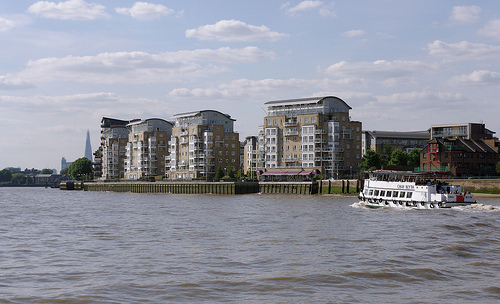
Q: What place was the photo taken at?
A: It was taken at the river.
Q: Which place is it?
A: It is a river.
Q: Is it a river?
A: Yes, it is a river.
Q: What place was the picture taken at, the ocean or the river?
A: It was taken at the river.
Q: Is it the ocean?
A: No, it is the river.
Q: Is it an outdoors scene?
A: Yes, it is outdoors.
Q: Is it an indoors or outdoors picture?
A: It is outdoors.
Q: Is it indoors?
A: No, it is outdoors.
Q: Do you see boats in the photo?
A: Yes, there is a boat.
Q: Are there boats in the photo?
A: Yes, there is a boat.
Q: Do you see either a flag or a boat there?
A: Yes, there is a boat.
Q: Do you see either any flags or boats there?
A: Yes, there is a boat.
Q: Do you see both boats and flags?
A: No, there is a boat but no flags.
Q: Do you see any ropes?
A: No, there are no ropes.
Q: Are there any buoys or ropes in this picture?
A: No, there are no ropes or buoys.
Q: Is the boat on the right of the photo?
A: Yes, the boat is on the right of the image.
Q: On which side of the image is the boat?
A: The boat is on the right of the image.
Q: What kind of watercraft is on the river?
A: The watercraft is a boat.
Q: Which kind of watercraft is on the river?
A: The watercraft is a boat.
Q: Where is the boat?
A: The boat is on the river.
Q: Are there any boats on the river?
A: Yes, there is a boat on the river.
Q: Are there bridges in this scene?
A: No, there are no bridges.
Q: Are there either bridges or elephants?
A: No, there are no bridges or elephants.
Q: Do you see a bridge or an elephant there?
A: No, there are no bridges or elephants.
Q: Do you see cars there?
A: No, there are no cars.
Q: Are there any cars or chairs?
A: No, there are no cars or chairs.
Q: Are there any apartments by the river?
A: Yes, there is an apartment by the river.